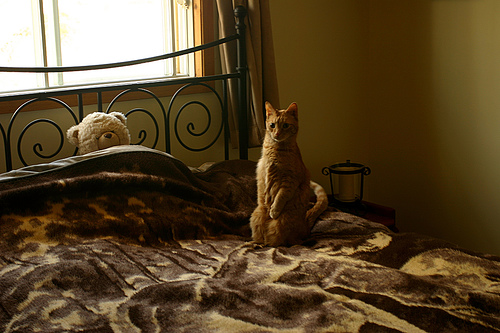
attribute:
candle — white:
[337, 160, 356, 198]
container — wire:
[317, 155, 377, 205]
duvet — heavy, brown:
[127, 183, 285, 328]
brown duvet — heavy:
[0, 142, 497, 331]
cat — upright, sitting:
[249, 100, 327, 242]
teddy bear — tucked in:
[66, 110, 132, 155]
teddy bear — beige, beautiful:
[65, 104, 134, 152]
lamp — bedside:
[318, 159, 372, 209]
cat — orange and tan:
[155, 55, 317, 280]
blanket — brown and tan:
[48, 190, 308, 317]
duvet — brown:
[2, 145, 497, 331]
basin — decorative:
[320, 156, 374, 208]